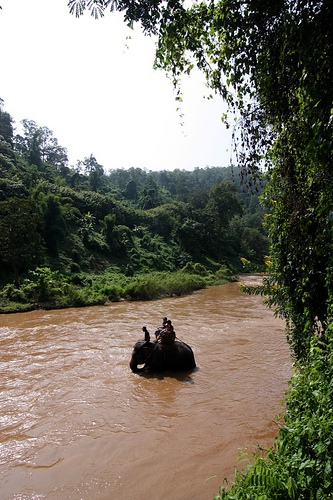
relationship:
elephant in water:
[128, 336, 196, 380] [71, 311, 160, 337]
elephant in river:
[128, 336, 196, 380] [110, 372, 218, 448]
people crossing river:
[140, 325, 152, 343] [163, 262, 279, 366]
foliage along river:
[212, 316, 330, 498] [1, 270, 330, 497]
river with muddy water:
[3, 275, 294, 454] [77, 409, 160, 443]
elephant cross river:
[128, 336, 196, 380] [130, 264, 321, 370]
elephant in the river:
[78, 305, 213, 392] [0, 271, 325, 498]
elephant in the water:
[128, 336, 196, 380] [28, 308, 270, 458]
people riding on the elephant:
[140, 325, 152, 343] [126, 317, 205, 385]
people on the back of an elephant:
[142, 323, 147, 341] [127, 335, 198, 374]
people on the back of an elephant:
[140, 325, 152, 343] [127, 335, 198, 374]